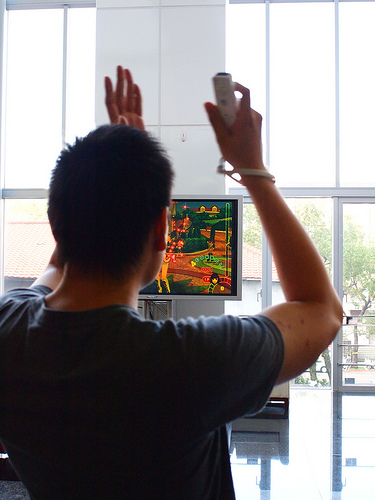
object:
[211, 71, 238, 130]
remote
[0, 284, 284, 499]
shirt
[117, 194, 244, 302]
tv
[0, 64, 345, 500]
person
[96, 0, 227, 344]
wall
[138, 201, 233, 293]
game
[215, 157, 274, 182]
lanyard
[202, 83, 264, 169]
hands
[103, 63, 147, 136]
hands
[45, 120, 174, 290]
head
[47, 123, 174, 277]
hair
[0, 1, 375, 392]
windows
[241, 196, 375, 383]
tree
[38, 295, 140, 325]
collar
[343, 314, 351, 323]
handle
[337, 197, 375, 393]
door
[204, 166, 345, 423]
arm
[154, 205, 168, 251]
ear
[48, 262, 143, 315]
neck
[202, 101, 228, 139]
thumb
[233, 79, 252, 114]
finger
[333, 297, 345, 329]
elbow